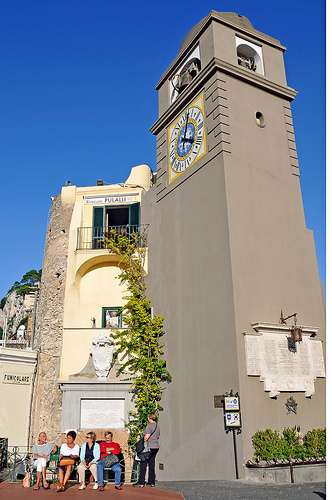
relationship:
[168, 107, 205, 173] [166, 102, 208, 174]
clock face of clock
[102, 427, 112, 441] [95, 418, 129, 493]
head of man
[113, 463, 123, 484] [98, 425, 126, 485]
leg of man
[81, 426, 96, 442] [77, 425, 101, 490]
head of woman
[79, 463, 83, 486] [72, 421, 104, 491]
leg of woman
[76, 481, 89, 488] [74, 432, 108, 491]
white shoe on woman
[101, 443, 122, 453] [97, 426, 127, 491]
red shirt on man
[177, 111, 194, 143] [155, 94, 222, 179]
black hands on clock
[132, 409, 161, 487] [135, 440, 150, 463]
woman carries crossbody bag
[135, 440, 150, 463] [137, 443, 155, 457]
crossbody bag possibly with toddler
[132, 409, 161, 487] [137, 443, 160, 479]
woman in black pants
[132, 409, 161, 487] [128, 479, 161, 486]
woman wears clogs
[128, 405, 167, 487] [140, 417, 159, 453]
woman wears grey top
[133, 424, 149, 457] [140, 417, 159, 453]
crossbody bag across grey top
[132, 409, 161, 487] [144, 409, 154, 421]
woman has blonde hair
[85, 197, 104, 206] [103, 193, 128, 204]
word before pulalli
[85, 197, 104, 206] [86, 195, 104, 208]
word  ristorante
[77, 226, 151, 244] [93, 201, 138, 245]
small balcony before wine bar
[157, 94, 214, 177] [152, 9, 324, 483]
clock on side of building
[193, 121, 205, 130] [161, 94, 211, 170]
roman numeral on clock face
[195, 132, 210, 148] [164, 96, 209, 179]
roman numeral on clock face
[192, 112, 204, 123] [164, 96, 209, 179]
roman numeral on clock face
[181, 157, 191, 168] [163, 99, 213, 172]
roman numeral on clock face